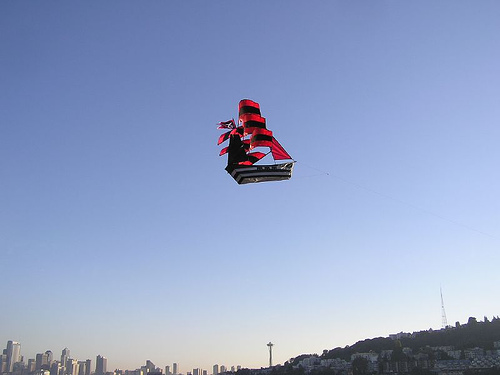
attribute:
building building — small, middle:
[141, 350, 253, 373]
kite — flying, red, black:
[212, 97, 297, 187]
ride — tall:
[264, 338, 276, 373]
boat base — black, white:
[227, 163, 293, 184]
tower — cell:
[432, 287, 460, 331]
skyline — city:
[2, 318, 284, 372]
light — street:
[260, 340, 288, 374]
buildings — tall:
[8, 331, 52, 373]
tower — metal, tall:
[266, 342, 273, 367]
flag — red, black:
[217, 118, 234, 131]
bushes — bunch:
[428, 329, 480, 340]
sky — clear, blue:
[1, 0, 498, 371]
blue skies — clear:
[0, 0, 494, 371]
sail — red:
[269, 137, 296, 163]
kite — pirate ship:
[180, 90, 303, 186]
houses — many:
[312, 326, 484, 374]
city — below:
[1, 283, 498, 373]